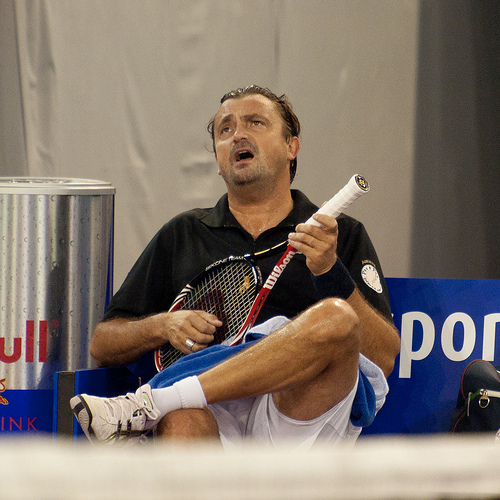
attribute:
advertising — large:
[0, 137, 125, 453]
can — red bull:
[8, 194, 169, 466]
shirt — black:
[106, 193, 411, 364]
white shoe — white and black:
[68, 381, 160, 443]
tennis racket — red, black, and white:
[152, 246, 286, 366]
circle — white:
[362, 264, 382, 294]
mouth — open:
[232, 146, 264, 165]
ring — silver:
[181, 332, 199, 350]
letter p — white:
[398, 309, 436, 379]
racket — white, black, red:
[152, 170, 369, 378]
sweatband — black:
[311, 261, 359, 300]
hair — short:
[205, 84, 305, 133]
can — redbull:
[1, 179, 116, 441]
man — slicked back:
[198, 74, 383, 289]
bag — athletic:
[451, 355, 499, 428]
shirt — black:
[101, 186, 399, 376]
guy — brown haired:
[70, 84, 398, 456]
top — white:
[17, 443, 485, 483]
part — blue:
[29, 328, 47, 420]